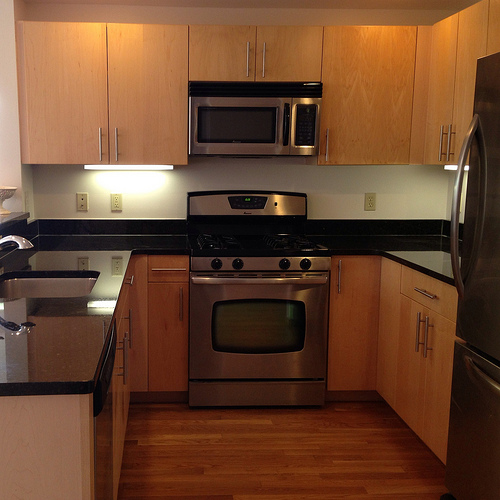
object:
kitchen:
[0, 0, 499, 499]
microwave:
[185, 82, 323, 158]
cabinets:
[188, 27, 323, 80]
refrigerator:
[435, 56, 500, 494]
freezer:
[448, 343, 497, 499]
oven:
[183, 271, 327, 411]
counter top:
[2, 221, 460, 390]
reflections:
[89, 297, 117, 317]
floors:
[124, 403, 384, 498]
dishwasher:
[93, 326, 120, 499]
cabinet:
[316, 23, 416, 169]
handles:
[320, 132, 335, 164]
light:
[81, 162, 176, 172]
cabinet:
[13, 22, 189, 170]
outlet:
[111, 193, 124, 216]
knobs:
[205, 256, 224, 271]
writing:
[239, 195, 256, 203]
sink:
[1, 270, 98, 302]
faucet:
[0, 225, 39, 257]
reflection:
[2, 308, 35, 339]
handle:
[451, 109, 478, 299]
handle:
[457, 357, 499, 395]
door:
[185, 270, 334, 386]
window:
[211, 299, 306, 350]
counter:
[28, 212, 189, 254]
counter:
[3, 233, 270, 324]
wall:
[36, 171, 446, 219]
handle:
[187, 273, 328, 285]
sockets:
[112, 202, 124, 212]